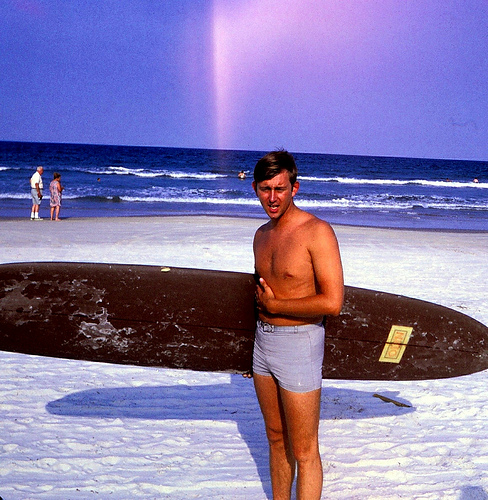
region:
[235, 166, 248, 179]
A person in the ocean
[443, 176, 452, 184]
A person in the ocean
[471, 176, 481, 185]
A person in the ocean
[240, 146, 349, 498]
a shirtless man on a beach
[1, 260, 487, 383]
a long brown surfboard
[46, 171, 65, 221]
a woman standing on a beach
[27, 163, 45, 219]
a man standing on a beach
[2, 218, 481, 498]
a white, sandy beach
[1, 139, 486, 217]
the ocean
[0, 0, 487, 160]
a clear, blue sky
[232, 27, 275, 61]
par tof a light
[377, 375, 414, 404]
part of a shade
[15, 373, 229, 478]
The snow on the ground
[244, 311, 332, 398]
The man has on short shorts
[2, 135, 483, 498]
The man is holding a surf board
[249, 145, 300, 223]
The head of the man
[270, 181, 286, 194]
The eye of the man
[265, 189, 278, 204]
The nose of the man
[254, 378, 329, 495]
The legs of the man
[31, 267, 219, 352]
The surfboard is brown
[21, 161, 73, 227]
The couple standing on the beach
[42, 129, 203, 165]
The ocean water is the color blue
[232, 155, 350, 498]
shirtless surfer on beach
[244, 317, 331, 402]
tight gray shorts on surfer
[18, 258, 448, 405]
long surfboard in hand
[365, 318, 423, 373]
yellow sticker on board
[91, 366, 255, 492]
footprints in white sand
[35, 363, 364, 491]
white sandy beach below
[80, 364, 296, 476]
shadow of man on sand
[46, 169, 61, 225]
woman in background by water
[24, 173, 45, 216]
man in background by water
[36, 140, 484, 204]
rough ocean in background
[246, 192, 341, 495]
MAN IS STANDING IN SAND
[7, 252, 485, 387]
MAN IS HOLDING LARGE SURFBOARD WITH ON HAND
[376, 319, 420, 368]
SURFBOARD HAS YELLOW STICKER ON IT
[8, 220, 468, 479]
THE SAND IS WHITE IN COLOR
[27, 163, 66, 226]
MAN AND WOMAN STANDING AT WATER LINE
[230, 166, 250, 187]
ONE PERSON IN WATER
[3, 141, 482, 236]
BODY OF WATER IS THE OCEAN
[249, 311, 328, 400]
MAN IS WEARING GRAY SWIM TRUNKS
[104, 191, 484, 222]
WAVES ARE BREAKING ON THE BEACH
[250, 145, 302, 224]
MAN APPEARS TO BE TALKING